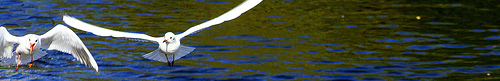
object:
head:
[26, 36, 45, 44]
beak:
[27, 43, 35, 54]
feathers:
[160, 53, 177, 66]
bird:
[61, 0, 263, 66]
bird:
[0, 24, 101, 75]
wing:
[40, 24, 99, 71]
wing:
[60, 15, 156, 40]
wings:
[182, 0, 261, 34]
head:
[159, 32, 180, 44]